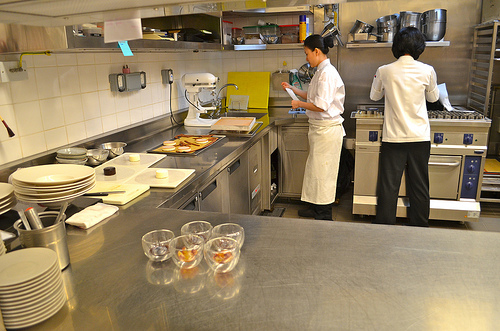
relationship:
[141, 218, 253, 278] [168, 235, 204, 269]
pancake syrup in bowl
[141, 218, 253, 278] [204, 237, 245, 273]
pancake syrup in bowl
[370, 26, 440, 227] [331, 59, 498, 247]
chef standing in front of stove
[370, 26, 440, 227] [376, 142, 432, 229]
chef wearing pants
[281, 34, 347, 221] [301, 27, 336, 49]
chef has hair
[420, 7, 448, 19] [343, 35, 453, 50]
bowl on shelf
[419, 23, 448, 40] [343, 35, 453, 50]
bowl on shelf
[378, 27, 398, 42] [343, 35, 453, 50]
bowl on shelf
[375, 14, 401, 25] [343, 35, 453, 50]
bowl on shelf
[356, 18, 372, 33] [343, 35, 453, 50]
bowl on shelf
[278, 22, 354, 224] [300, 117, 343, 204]
chef wearing apron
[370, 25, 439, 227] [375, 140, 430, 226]
chef wearing black pants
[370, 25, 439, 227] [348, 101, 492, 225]
chef cooking at stove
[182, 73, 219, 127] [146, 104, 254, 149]
blender on counter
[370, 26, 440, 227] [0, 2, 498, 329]
chef in kitchen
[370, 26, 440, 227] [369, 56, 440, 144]
chef wearing jacket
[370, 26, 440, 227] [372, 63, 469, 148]
chef wearing jacket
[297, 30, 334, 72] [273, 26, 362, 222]
head on woman